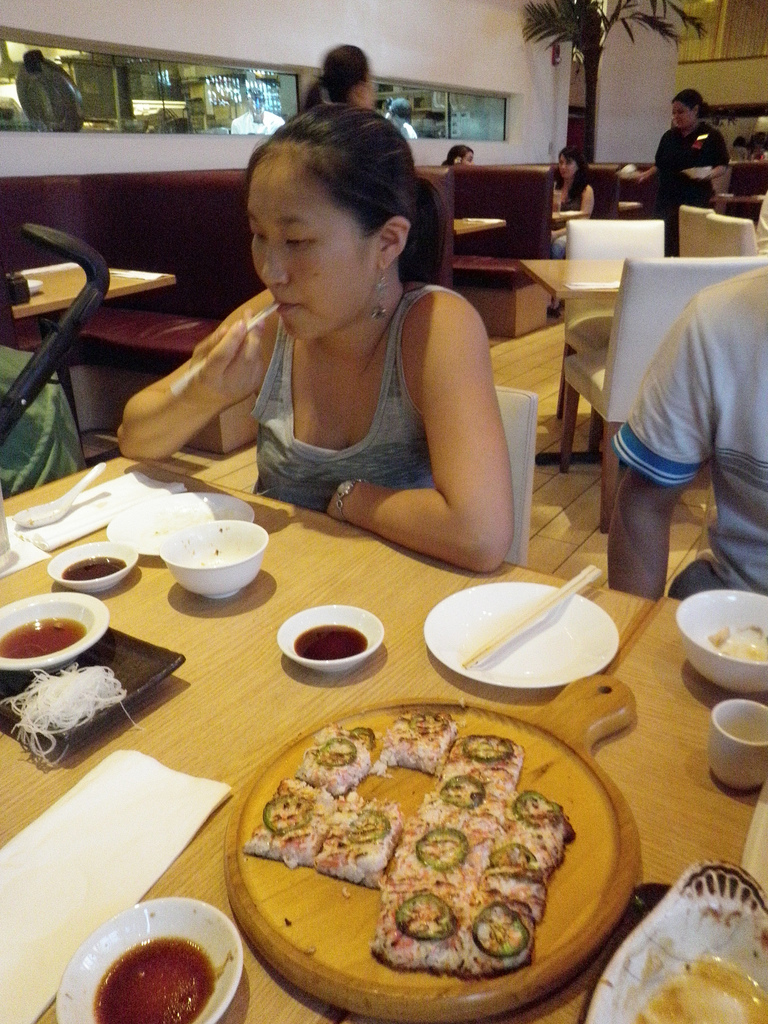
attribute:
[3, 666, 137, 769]
noodle — rice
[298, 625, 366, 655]
sauce — brown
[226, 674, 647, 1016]
board — wooden, serving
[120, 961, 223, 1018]
sauce — red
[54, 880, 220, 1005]
bowl — white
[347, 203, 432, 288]
ear — woman's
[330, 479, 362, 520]
wrist — woman's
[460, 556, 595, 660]
chopstick — wood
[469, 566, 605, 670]
chopstick — wood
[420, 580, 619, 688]
plate — white